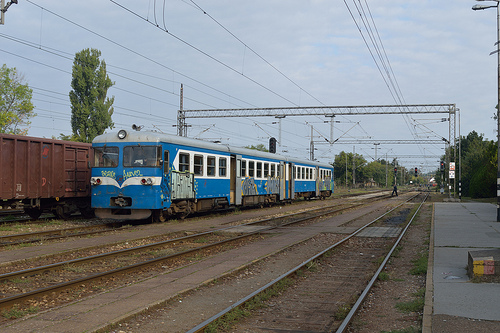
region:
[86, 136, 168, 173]
the windshield of the train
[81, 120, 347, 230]
the train is blue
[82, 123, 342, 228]
this is a train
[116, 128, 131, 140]
this is a light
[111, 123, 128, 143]
the light is round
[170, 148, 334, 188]
the train has many windows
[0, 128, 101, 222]
the train car is brown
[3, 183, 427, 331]
the train is on the tracks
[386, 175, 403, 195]
the person is on the tracks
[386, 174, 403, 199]
the train is walking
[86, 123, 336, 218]
THE TRAIN IS BLUE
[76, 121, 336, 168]
THE ROOF ON THE TRAIN IS WHITE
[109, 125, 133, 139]
THE LIGHT IS ON THE TRAIN2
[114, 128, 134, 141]
THIS IS A LIGHT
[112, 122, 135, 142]
THE LIGHT IS ROUND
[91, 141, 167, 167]
THIS IS THE WINDSHIELD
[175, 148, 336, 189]
THESE ARE WINDOWS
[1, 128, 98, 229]
THE TRAIN CAR IS BROWN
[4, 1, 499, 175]
THE SKY IS LIGHT BLUE WITH LITTLE CLOUDS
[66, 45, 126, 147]
THE TREE IS TALL AND GREEN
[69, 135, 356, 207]
a train is parked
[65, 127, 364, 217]
the train is blue and white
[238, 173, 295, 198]
graffiti on the side of train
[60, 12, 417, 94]
wires above the train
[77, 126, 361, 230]
the train is empty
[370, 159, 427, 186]
the lights are red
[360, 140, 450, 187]
three traffic lights in the distance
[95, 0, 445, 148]
the sky is overcast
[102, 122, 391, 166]
the top of the train is grey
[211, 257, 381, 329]
grass growing on the tracks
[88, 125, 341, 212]
a blue and white train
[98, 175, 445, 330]
train tracks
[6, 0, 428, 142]
multiple phone cables and other cables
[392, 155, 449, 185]
red traffic stop lights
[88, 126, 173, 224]
the front of a train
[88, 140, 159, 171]
two windshields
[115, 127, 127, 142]
a light that is turned off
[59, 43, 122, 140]
a tall green tree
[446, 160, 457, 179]
a red and white sign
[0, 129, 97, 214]
a brown box car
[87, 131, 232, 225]
a bright blue and white train car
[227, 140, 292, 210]
a bright blue and white train car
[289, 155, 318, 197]
a bright blue and white train car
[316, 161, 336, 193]
a bright blue and white train car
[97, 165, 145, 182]
the yellow writing on a train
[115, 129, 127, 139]
a round head light on a train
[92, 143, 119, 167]
the window of a train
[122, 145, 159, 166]
the window of a train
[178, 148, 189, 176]
the window of a train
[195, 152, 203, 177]
the window of a train